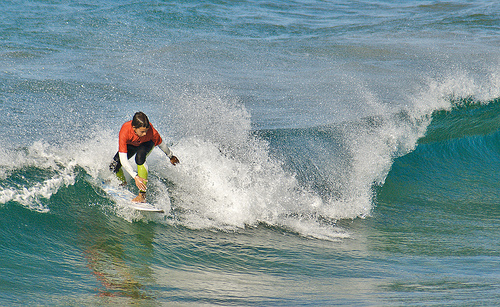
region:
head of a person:
[128, 106, 157, 136]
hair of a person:
[132, 106, 149, 121]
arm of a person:
[150, 123, 182, 162]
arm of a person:
[110, 130, 142, 176]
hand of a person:
[125, 178, 150, 191]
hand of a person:
[163, 154, 183, 165]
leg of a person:
[131, 143, 147, 202]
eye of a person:
[139, 125, 145, 135]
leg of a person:
[128, 194, 148, 206]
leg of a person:
[82, 148, 126, 194]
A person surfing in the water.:
[90, 96, 177, 206]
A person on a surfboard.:
[73, 155, 140, 213]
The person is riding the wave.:
[49, 103, 185, 222]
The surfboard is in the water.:
[113, 192, 178, 224]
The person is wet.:
[106, 101, 210, 207]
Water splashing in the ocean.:
[140, 75, 282, 172]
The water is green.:
[90, 221, 462, 293]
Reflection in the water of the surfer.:
[76, 211, 213, 287]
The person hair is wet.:
[121, 104, 168, 121]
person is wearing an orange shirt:
[113, 115, 164, 150]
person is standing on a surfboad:
[108, 105, 162, 218]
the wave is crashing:
[206, 171, 366, 231]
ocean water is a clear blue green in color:
[413, 135, 483, 185]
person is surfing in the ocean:
[81, 103, 191, 215]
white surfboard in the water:
[111, 184, 174, 225]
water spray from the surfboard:
[82, 110, 114, 142]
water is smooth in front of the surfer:
[263, 255, 450, 305]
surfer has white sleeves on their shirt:
[112, 150, 139, 175]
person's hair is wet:
[128, 103, 148, 126]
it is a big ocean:
[220, 6, 460, 264]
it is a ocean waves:
[186, 100, 291, 217]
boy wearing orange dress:
[115, 105, 167, 142]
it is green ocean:
[70, 237, 420, 298]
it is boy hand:
[115, 166, 154, 193]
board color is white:
[82, 191, 163, 232]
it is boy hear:
[129, 104, 148, 131]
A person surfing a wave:
[100, 95, 188, 226]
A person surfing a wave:
[106, 102, 186, 218]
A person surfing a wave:
[103, 96, 183, 226]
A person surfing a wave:
[105, 105, 181, 222]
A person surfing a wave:
[102, 92, 182, 220]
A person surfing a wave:
[95, 98, 181, 218]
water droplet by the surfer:
[220, 142, 235, 157]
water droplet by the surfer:
[244, 148, 251, 158]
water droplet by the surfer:
[236, 98, 244, 112]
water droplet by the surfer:
[5, 108, 10, 118]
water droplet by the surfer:
[78, 82, 85, 93]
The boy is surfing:
[108, 109, 192, 203]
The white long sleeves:
[117, 151, 139, 180]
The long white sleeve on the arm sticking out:
[161, 139, 173, 159]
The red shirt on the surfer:
[119, 116, 164, 154]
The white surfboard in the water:
[91, 175, 166, 213]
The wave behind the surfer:
[1, 95, 496, 240]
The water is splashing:
[77, 131, 318, 230]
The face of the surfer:
[138, 126, 149, 138]